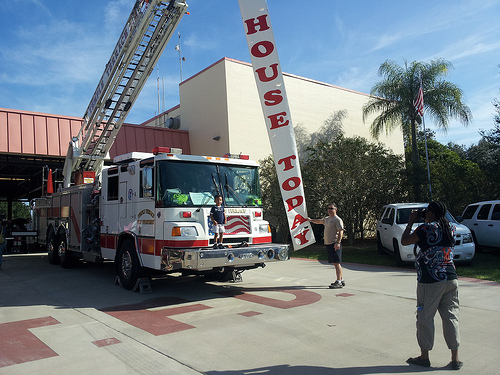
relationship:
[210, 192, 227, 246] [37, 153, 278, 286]
boy standing on truck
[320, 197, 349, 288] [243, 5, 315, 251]
man standing by sign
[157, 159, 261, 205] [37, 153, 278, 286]
windshield of truck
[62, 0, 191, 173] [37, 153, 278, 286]
ladder of truck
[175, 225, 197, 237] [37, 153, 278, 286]
headlight on front of truck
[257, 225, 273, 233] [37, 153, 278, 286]
headlight on front of truck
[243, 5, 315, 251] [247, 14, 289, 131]
sign reads house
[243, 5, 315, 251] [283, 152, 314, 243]
sign reads today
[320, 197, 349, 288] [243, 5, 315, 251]
man holding sign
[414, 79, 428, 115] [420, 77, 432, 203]
flag on top of pole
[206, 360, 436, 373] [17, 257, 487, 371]
shadow on top of ground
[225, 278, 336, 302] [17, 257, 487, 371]
shadow on top of ground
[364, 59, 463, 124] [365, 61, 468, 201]
leaves on top of tree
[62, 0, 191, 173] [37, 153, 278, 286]
ladder on top of truck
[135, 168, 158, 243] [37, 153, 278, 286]
door of truck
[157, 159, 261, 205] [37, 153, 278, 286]
windshield on front of truck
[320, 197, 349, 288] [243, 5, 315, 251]
man near sign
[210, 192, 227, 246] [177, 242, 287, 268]
boy on top of bumper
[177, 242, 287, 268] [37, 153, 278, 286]
bumper of truck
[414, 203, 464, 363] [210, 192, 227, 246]
mother of boy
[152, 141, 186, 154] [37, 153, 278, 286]
lights on top of truck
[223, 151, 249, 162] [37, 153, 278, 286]
lights on top of truck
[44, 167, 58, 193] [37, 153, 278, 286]
cone on side of truck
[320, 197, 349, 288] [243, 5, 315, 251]
man beside sign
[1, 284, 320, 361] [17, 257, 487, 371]
letters on cement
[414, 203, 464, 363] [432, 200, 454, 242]
woman with dreads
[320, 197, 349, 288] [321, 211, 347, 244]
man in shirt